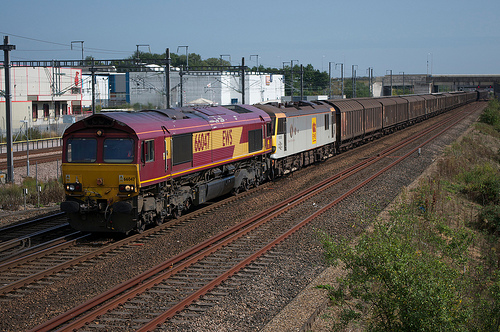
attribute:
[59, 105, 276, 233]
engine — red, dark red, yellow, first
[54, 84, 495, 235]
train — long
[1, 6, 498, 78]
sky — clear, blue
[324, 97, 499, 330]
foliage — green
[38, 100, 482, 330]
tracks — rusty, well-worn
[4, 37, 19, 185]
pole — telephone tower, power line, gray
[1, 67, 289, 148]
building — white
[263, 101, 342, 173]
secondary engine — grey, gray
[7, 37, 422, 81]
wires — overhead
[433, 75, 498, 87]
bridge — distant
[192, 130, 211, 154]
numbers — 66047, red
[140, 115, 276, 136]
stripe — yellow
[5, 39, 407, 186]
poles — wooden